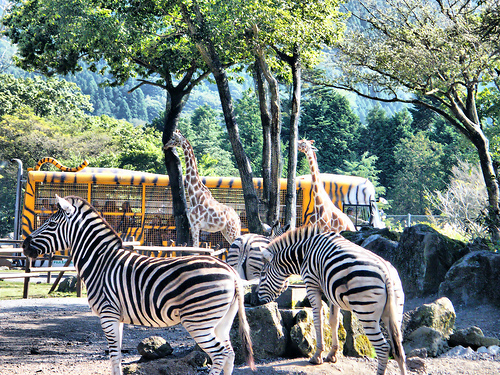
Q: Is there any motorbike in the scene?
A: No, there are no motorcycles.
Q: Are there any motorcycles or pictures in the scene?
A: No, there are no motorcycles or pictures.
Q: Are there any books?
A: No, there are no books.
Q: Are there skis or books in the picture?
A: No, there are no books or skis.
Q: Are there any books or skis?
A: No, there are no books or skis.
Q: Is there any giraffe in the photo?
A: Yes, there are giraffes.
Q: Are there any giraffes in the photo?
A: Yes, there are giraffes.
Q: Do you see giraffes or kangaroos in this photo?
A: Yes, there are giraffes.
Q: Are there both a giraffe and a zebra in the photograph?
A: Yes, there are both a giraffe and a zebra.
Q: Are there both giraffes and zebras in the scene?
A: Yes, there are both giraffes and zebras.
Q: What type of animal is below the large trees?
A: The animals are giraffes.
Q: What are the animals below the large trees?
A: The animals are giraffes.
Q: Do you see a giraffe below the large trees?
A: Yes, there are giraffes below the trees.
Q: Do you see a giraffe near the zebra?
A: Yes, there are giraffes near the zebra.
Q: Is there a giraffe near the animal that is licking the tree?
A: Yes, there are giraffes near the zebra.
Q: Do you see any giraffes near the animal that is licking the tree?
A: Yes, there are giraffes near the zebra.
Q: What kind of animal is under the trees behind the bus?
A: The animals are giraffes.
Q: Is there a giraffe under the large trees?
A: Yes, there are giraffes under the trees.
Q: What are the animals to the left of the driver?
A: The animals are giraffes.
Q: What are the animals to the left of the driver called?
A: The animals are giraffes.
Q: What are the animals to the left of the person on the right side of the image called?
A: The animals are giraffes.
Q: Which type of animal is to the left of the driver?
A: The animals are giraffes.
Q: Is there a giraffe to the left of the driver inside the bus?
A: Yes, there are giraffes to the left of the driver.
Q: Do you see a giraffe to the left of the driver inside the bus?
A: Yes, there are giraffes to the left of the driver.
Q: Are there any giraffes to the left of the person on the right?
A: Yes, there are giraffes to the left of the driver.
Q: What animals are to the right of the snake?
A: The animals are giraffes.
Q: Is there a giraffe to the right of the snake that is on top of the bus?
A: Yes, there are giraffes to the right of the snake.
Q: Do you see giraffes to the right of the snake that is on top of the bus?
A: Yes, there are giraffes to the right of the snake.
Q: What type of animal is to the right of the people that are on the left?
A: The animals are giraffes.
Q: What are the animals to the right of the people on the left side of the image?
A: The animals are giraffes.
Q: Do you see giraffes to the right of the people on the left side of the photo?
A: Yes, there are giraffes to the right of the people.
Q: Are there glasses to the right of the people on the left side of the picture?
A: No, there are giraffes to the right of the people.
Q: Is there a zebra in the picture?
A: Yes, there is a zebra.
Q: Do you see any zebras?
A: Yes, there is a zebra.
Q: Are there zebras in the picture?
A: Yes, there is a zebra.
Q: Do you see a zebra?
A: Yes, there is a zebra.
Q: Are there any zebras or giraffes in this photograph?
A: Yes, there is a zebra.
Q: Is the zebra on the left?
A: Yes, the zebra is on the left of the image.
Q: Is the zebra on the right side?
A: No, the zebra is on the left of the image.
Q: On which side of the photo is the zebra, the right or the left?
A: The zebra is on the left of the image.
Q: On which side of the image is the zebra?
A: The zebra is on the left of the image.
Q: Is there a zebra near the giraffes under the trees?
A: Yes, there is a zebra near the giraffes.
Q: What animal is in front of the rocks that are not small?
A: The zebra is in front of the rocks.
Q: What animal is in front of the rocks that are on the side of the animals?
A: The animal is a zebra.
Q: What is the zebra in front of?
A: The zebra is in front of the rocks.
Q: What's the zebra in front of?
A: The zebra is in front of the rocks.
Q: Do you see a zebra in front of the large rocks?
A: Yes, there is a zebra in front of the rocks.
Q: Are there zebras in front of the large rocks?
A: Yes, there is a zebra in front of the rocks.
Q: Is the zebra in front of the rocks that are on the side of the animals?
A: Yes, the zebra is in front of the rocks.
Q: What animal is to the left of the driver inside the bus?
A: The animal is a zebra.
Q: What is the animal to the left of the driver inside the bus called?
A: The animal is a zebra.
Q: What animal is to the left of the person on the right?
A: The animal is a zebra.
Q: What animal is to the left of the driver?
A: The animal is a zebra.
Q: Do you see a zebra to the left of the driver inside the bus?
A: Yes, there is a zebra to the left of the driver.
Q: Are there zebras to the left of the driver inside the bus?
A: Yes, there is a zebra to the left of the driver.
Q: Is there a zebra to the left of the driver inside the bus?
A: Yes, there is a zebra to the left of the driver.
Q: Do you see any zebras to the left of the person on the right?
A: Yes, there is a zebra to the left of the driver.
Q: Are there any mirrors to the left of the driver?
A: No, there is a zebra to the left of the driver.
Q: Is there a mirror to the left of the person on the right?
A: No, there is a zebra to the left of the driver.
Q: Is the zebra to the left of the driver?
A: Yes, the zebra is to the left of the driver.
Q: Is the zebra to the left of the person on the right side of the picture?
A: Yes, the zebra is to the left of the driver.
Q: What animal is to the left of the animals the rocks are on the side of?
A: The animal is a zebra.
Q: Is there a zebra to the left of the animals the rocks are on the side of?
A: Yes, there is a zebra to the left of the animals.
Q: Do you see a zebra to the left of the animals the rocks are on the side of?
A: Yes, there is a zebra to the left of the animals.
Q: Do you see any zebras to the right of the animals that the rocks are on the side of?
A: No, the zebra is to the left of the animals.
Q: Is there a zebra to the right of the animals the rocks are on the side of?
A: No, the zebra is to the left of the animals.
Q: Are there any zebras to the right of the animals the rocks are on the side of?
A: No, the zebra is to the left of the animals.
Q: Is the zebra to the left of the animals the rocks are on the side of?
A: Yes, the zebra is to the left of the animals.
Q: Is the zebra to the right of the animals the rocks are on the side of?
A: No, the zebra is to the left of the animals.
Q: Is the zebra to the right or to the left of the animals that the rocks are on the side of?
A: The zebra is to the left of the animals.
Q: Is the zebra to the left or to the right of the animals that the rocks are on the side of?
A: The zebra is to the left of the animals.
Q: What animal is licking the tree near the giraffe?
A: The zebra is licking the tree.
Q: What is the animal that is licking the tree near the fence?
A: The animal is a zebra.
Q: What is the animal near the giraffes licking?
A: The zebra is licking the tree.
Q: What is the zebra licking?
A: The zebra is licking the tree.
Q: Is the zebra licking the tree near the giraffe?
A: Yes, the zebra is licking the tree.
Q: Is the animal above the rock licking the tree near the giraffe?
A: Yes, the zebra is licking the tree.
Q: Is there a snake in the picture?
A: Yes, there is a snake.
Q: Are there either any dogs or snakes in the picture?
A: Yes, there is a snake.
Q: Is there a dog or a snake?
A: Yes, there is a snake.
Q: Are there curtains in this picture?
A: No, there are no curtains.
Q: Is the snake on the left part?
A: Yes, the snake is on the left of the image.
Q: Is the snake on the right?
A: No, the snake is on the left of the image.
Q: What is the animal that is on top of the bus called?
A: The animal is a snake.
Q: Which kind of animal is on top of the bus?
A: The animal is a snake.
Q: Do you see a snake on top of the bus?
A: Yes, there is a snake on top of the bus.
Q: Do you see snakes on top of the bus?
A: Yes, there is a snake on top of the bus.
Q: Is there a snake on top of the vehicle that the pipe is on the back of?
A: Yes, there is a snake on top of the bus.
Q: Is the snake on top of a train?
A: No, the snake is on top of the bus.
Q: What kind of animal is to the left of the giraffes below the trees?
A: The animal is a snake.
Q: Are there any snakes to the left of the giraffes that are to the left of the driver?
A: Yes, there is a snake to the left of the giraffes.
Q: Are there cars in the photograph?
A: No, there are no cars.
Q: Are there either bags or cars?
A: No, there are no cars or bags.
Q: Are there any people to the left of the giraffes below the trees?
A: Yes, there are people to the left of the giraffes.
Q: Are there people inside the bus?
A: Yes, there are people inside the bus.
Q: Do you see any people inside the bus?
A: Yes, there are people inside the bus.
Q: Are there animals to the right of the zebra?
A: Yes, there are animals to the right of the zebra.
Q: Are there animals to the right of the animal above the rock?
A: Yes, there are animals to the right of the zebra.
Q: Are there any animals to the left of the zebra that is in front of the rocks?
A: No, the animals are to the right of the zebra.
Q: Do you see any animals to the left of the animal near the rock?
A: No, the animals are to the right of the zebra.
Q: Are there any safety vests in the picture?
A: No, there are no safety vests.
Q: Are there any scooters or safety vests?
A: No, there are no safety vests or scooters.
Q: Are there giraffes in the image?
A: Yes, there is a giraffe.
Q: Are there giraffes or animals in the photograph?
A: Yes, there is a giraffe.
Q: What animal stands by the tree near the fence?
A: The giraffe stands by the tree.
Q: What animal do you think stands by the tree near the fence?
A: The animal is a giraffe.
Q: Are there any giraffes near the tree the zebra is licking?
A: Yes, there is a giraffe near the tree.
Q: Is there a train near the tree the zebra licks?
A: No, there is a giraffe near the tree.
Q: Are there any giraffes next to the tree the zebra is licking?
A: Yes, there is a giraffe next to the tree.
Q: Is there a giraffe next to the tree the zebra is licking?
A: Yes, there is a giraffe next to the tree.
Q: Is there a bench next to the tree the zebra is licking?
A: No, there is a giraffe next to the tree.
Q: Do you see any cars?
A: No, there are no cars.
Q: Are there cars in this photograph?
A: No, there are no cars.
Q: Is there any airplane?
A: No, there are no airplanes.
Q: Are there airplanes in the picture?
A: No, there are no airplanes.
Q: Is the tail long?
A: Yes, the tail is long.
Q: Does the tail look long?
A: Yes, the tail is long.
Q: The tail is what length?
A: The tail is long.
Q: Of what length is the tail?
A: The tail is long.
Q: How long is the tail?
A: The tail is long.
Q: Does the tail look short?
A: No, the tail is long.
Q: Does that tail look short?
A: No, the tail is long.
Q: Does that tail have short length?
A: No, the tail is long.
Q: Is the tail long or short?
A: The tail is long.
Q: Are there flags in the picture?
A: No, there are no flags.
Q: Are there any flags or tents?
A: No, there are no flags or tents.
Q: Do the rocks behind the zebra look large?
A: Yes, the rocks are large.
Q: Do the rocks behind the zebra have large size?
A: Yes, the rocks are large.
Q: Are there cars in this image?
A: No, there are no cars.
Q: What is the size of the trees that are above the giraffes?
A: The trees are large.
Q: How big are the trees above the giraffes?
A: The trees are large.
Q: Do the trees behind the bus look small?
A: No, the trees are large.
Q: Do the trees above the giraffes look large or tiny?
A: The trees are large.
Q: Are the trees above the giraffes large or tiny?
A: The trees are large.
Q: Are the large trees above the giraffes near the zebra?
A: Yes, the trees are above the giraffes.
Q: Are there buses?
A: Yes, there is a bus.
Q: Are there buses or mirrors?
A: Yes, there is a bus.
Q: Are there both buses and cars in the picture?
A: No, there is a bus but no cars.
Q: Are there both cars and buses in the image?
A: No, there is a bus but no cars.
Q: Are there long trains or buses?
A: Yes, there is a long bus.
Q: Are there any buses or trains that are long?
A: Yes, the bus is long.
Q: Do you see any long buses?
A: Yes, there is a long bus.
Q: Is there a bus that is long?
A: Yes, there is a bus that is long.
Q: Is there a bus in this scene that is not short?
A: Yes, there is a long bus.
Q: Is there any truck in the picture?
A: No, there are no trucks.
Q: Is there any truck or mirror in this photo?
A: No, there are no trucks or mirrors.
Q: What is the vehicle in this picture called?
A: The vehicle is a bus.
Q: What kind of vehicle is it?
A: The vehicle is a bus.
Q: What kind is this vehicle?
A: This is a bus.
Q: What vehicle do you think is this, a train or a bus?
A: This is a bus.